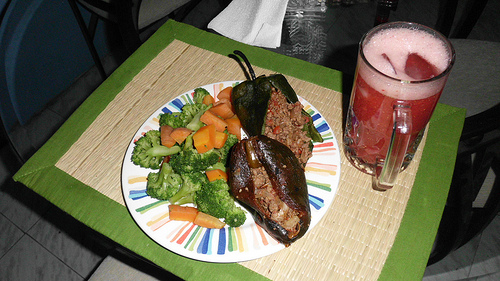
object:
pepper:
[231, 49, 324, 169]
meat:
[250, 167, 301, 238]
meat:
[264, 88, 313, 167]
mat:
[11, 20, 467, 281]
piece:
[161, 87, 240, 181]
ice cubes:
[381, 49, 408, 71]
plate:
[121, 81, 339, 264]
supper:
[131, 74, 324, 243]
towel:
[207, 0, 288, 48]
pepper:
[225, 135, 311, 245]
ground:
[0, 37, 500, 281]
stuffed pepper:
[231, 49, 323, 166]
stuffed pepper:
[227, 136, 310, 244]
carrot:
[160, 87, 241, 229]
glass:
[343, 21, 456, 189]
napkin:
[206, 0, 288, 49]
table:
[14, 20, 467, 281]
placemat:
[12, 20, 466, 281]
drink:
[351, 27, 451, 163]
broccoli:
[131, 88, 246, 227]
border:
[376, 102, 466, 281]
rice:
[263, 89, 312, 166]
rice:
[250, 168, 300, 236]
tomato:
[273, 125, 279, 134]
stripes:
[128, 82, 337, 256]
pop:
[349, 28, 449, 163]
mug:
[344, 21, 453, 190]